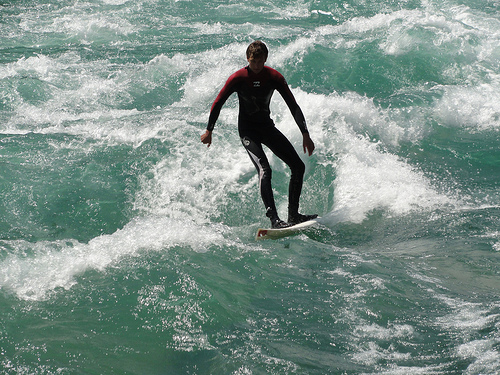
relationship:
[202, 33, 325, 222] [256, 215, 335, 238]
man riding surfboard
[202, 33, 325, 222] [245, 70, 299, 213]
man wearing wetsuit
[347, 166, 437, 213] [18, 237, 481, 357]
wave cap inside of ocean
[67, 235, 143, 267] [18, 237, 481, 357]
sea foam on top of ocean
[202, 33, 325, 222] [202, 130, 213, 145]
man has hand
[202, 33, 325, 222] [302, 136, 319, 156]
man has hand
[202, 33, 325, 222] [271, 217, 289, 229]
man has foot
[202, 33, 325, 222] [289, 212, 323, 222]
man has foot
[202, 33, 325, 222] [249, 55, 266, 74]
man has face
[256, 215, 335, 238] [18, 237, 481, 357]
surfboard floating on ocean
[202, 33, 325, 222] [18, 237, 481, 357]
man surfing in ocean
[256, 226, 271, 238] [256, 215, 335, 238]
tip of surfboard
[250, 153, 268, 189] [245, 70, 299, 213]
stripe on wetsuit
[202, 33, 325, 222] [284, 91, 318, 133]
man extending arm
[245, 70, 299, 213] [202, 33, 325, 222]
wetsuit on man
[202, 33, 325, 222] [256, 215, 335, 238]
man surfing on surfboard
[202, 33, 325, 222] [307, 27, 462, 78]
man surfing on wave